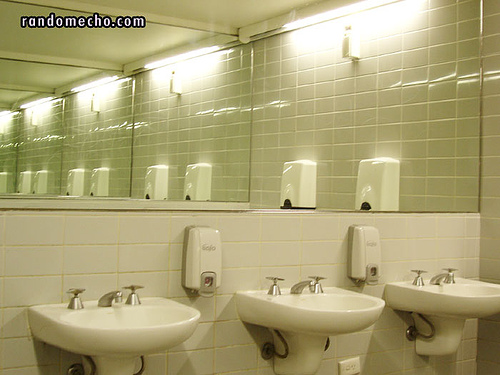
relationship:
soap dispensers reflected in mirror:
[354, 153, 404, 208] [46, 21, 464, 186]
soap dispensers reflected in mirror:
[279, 157, 317, 205] [46, 21, 464, 186]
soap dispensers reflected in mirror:
[182, 158, 209, 202] [46, 21, 464, 186]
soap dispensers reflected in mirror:
[146, 167, 168, 194] [46, 21, 464, 186]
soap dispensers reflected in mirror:
[88, 167, 105, 194] [46, 21, 464, 186]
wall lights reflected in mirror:
[226, 0, 441, 42] [97, 45, 367, 191]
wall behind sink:
[5, 198, 484, 359] [25, 239, 216, 374]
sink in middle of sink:
[27, 283, 201, 373] [237, 285, 384, 373]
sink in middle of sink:
[27, 283, 201, 373] [381, 269, 498, 356]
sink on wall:
[237, 285, 384, 373] [1, 217, 482, 368]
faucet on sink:
[95, 283, 149, 307] [25, 287, 209, 372]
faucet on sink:
[258, 273, 344, 298] [237, 285, 384, 373]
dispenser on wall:
[181, 227, 226, 300] [5, 198, 484, 359]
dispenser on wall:
[339, 216, 399, 293] [5, 198, 484, 359]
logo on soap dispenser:
[199, 239, 219, 254] [183, 250, 226, 302]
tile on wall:
[402, 81, 429, 106] [249, 1, 489, 204]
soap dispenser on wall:
[178, 215, 228, 302] [1, 217, 482, 368]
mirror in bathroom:
[5, 1, 492, 217] [2, 6, 498, 372]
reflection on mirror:
[144, 4, 413, 99] [154, 51, 406, 175]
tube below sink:
[134, 354, 149, 374] [25, 295, 200, 357]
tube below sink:
[83, 354, 97, 374] [25, 295, 200, 357]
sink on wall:
[237, 285, 384, 373] [1, 4, 498, 372]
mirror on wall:
[5, 1, 492, 217] [1, 4, 498, 372]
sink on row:
[27, 283, 201, 373] [21, 263, 498, 370]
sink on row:
[237, 285, 384, 373] [21, 263, 498, 370]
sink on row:
[386, 267, 499, 359] [21, 263, 498, 370]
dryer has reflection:
[347, 150, 407, 216] [6, 149, 422, 218]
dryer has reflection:
[275, 153, 324, 213] [6, 149, 422, 218]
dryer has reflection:
[179, 156, 219, 204] [6, 149, 422, 218]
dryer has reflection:
[137, 164, 172, 203] [6, 149, 422, 218]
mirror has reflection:
[5, 1, 492, 217] [2, 4, 498, 216]